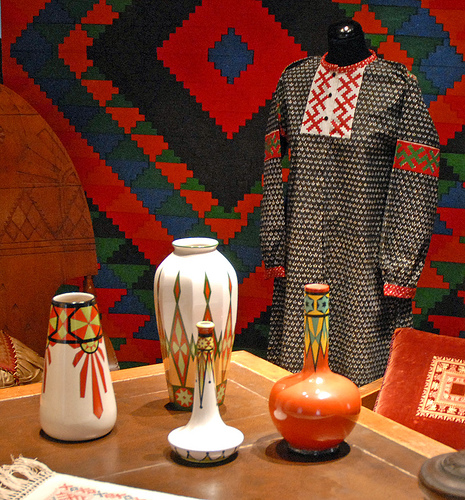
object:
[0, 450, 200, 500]
cloth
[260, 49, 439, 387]
costume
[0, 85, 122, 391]
chair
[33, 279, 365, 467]
line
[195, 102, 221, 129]
trim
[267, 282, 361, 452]
glass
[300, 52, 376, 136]
design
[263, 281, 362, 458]
bottles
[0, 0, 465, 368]
design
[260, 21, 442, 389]
mannequin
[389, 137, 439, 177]
design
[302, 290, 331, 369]
design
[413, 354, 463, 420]
design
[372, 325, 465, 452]
pillow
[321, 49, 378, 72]
symbols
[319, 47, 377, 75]
collar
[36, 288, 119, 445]
vase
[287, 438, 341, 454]
base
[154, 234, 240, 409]
vase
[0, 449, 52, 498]
fringe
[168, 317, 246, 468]
vase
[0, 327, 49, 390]
rug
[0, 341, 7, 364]
design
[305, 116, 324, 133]
line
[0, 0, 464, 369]
wall